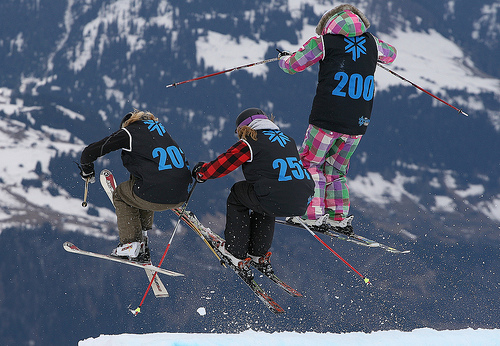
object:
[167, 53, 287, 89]
pole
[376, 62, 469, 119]
pole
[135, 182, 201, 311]
pole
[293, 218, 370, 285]
pole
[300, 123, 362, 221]
pants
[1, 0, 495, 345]
mountain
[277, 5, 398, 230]
person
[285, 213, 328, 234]
ski boots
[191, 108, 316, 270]
person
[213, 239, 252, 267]
ski boots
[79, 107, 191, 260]
person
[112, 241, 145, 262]
ski boots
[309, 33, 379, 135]
vest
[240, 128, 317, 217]
vest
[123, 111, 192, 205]
vest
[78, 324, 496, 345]
snow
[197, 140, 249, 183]
plaid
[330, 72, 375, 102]
200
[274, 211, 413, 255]
skis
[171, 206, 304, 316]
skis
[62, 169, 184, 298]
skis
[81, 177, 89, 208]
pole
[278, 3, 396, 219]
clothes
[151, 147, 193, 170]
202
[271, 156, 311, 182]
251